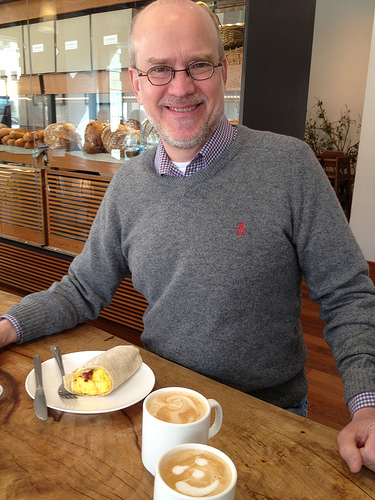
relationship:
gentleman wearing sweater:
[0, 0, 375, 476] [0, 124, 374, 406]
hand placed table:
[335, 401, 373, 474] [1, 288, 373, 498]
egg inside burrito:
[77, 370, 107, 398] [78, 352, 129, 404]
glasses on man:
[127, 54, 232, 100] [18, 38, 374, 491]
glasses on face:
[127, 54, 232, 100] [120, 15, 246, 138]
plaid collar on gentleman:
[143, 112, 242, 185] [0, 0, 375, 476]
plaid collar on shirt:
[143, 112, 242, 185] [1, 118, 373, 414]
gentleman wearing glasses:
[2, 2, 373, 475] [130, 59, 222, 86]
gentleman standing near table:
[0, 0, 375, 476] [207, 396, 316, 446]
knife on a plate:
[27, 350, 53, 425] [20, 343, 159, 421]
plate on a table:
[24, 351, 155, 414] [1, 280, 373, 483]